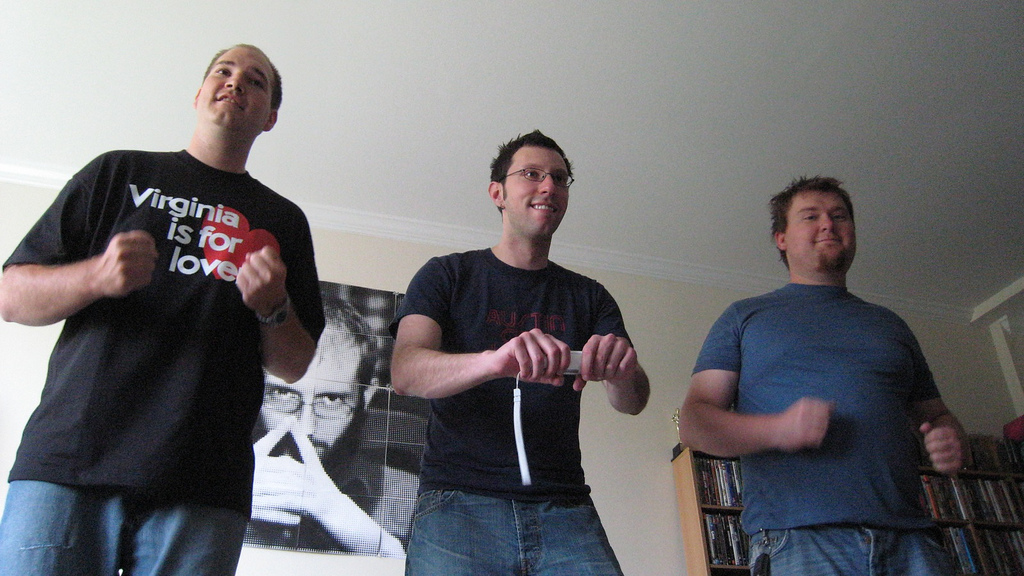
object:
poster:
[239, 278, 430, 560]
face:
[258, 326, 376, 467]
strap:
[510, 373, 534, 485]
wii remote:
[540, 350, 586, 375]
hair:
[202, 44, 284, 112]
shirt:
[0, 147, 328, 523]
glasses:
[498, 168, 574, 187]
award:
[670, 408, 679, 444]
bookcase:
[663, 419, 1021, 575]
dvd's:
[695, 458, 742, 507]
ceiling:
[0, 0, 1022, 325]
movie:
[977, 525, 1001, 575]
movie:
[706, 511, 749, 567]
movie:
[985, 478, 1002, 522]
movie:
[925, 474, 941, 521]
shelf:
[696, 503, 1024, 534]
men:
[0, 44, 325, 575]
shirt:
[690, 284, 961, 540]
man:
[388, 130, 650, 574]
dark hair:
[488, 128, 575, 222]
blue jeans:
[402, 489, 626, 575]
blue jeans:
[0, 475, 254, 575]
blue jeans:
[747, 523, 957, 575]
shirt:
[395, 247, 638, 506]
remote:
[509, 350, 588, 487]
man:
[378, 245, 632, 504]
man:
[679, 175, 966, 575]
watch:
[254, 296, 293, 328]